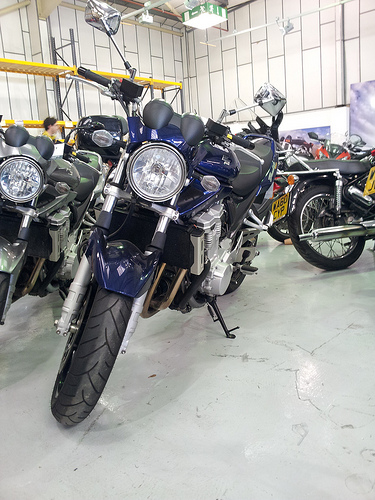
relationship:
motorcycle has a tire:
[50, 67, 277, 427] [50, 275, 131, 431]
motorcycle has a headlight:
[50, 67, 277, 427] [129, 142, 184, 206]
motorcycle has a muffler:
[50, 67, 277, 427] [295, 221, 371, 242]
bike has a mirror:
[52, 65, 277, 430] [86, 4, 121, 37]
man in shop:
[42, 118, 64, 141] [1, 2, 374, 495]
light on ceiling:
[180, 5, 226, 33] [114, 2, 247, 24]